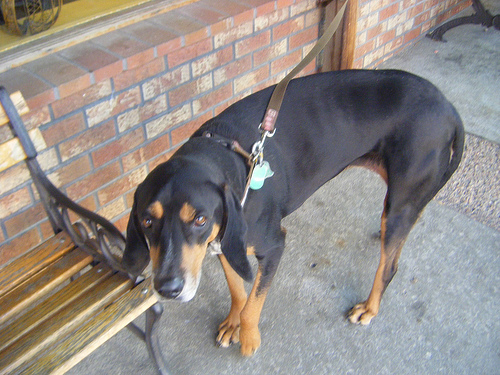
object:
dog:
[119, 68, 466, 320]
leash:
[245, 104, 285, 195]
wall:
[144, 32, 222, 106]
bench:
[5, 193, 137, 335]